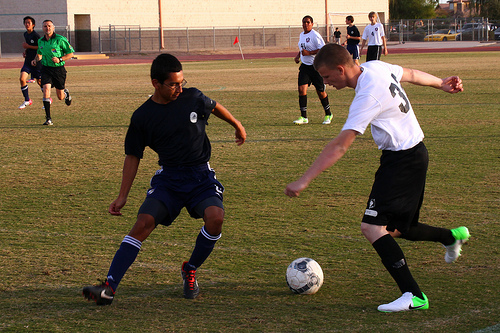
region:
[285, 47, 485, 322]
A man in white and black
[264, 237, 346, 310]
A white and blue soccer ball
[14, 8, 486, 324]
Multiple people on a grass field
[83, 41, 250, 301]
A man in dark blue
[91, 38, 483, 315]
Two soccer players fight for the ball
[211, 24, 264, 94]
A red flag marks the edge of the field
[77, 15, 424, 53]
A grey chain link fence runs alongside a building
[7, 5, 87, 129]
Two people run on the grass field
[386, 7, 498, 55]
A parking lot with cars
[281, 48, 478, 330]
The man wears knee high black socks with white and green cleats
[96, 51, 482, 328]
two men go after the same ball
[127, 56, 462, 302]
two men on opposing teams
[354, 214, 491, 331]
white and green nike shoes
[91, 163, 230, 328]
red and black nike cleets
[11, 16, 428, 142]
each team is trying to catch up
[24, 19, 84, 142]
ref is wearing a green shirt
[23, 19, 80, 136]
ref is wearing black shorts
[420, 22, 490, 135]
yellow car in background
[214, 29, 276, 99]
red flag on sidelines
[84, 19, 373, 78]
fence is in background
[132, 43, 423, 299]
Two players kicking a ball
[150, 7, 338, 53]
Orange goalposts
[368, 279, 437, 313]
Yellow and white soccer cleats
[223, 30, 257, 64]
A red flag at the edge of the field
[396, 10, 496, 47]
A chain link fence separating the parking lot from the field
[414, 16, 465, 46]
A yellow car in the parking lot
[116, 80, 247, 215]
A player wearing a black shirt and navy shorts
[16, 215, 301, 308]
Field lines painted on the ground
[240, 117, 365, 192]
Dry green grass covering a soccer field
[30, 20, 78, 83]
A man wearing a green soccer jersey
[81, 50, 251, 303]
a man in a blue shorts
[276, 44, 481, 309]
the player in black shorts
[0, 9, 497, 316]
a team of football players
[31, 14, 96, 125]
the referee of the football game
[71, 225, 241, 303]
one of the players in blue socks stripped white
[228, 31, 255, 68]
a red flag at the far end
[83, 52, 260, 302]
The player in wearing spectacles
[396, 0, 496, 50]
cars at the background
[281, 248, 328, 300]
the ball that the players are playing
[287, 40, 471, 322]
the player in white shirt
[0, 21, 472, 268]
Picture is taken outside.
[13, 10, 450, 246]
People are playing soccer.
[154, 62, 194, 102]
A man is wearing glasses.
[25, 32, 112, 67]
A man is wearing a green shirt.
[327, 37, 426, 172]
A man is wearing a white shirt.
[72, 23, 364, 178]
Picture taken during the daytime.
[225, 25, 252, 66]
A red flag in the grass.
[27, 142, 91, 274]
The grass is green.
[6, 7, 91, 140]
The men are running.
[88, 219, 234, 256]
His socks are blue with white stripes.